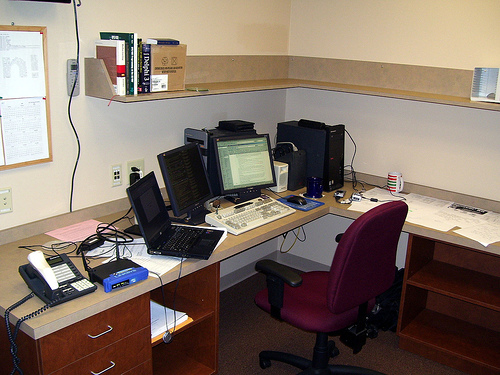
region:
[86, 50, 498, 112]
corner shelf above the desk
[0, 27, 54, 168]
bulletin board with papers on it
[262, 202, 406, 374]
maroon desk chair.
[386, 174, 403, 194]
red and green striped mug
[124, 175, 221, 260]
laptop on the desk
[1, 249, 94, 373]
black and white telephone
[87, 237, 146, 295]
black and blue computer router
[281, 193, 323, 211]
mouse on a blue mousepad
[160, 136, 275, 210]
two desktop computer monitors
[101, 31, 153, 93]
books on the left end of the shelf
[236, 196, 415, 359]
the chair is maroon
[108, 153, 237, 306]
the laptop on the table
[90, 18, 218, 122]
a book on the shelf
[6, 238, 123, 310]
a telephone on the desk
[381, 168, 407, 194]
green and red coffee cup on desk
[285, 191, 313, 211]
black computer mouse on a pad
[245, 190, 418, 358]
red office chair at a desk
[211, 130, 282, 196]
computer monitor on a desk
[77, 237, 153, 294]
black and blue computer router on desk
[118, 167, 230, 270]
laptop computer on a desk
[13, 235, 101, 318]
office telephone on a desk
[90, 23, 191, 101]
books on a shelf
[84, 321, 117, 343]
metal handle on a drawer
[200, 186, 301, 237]
computer keyboard on a desk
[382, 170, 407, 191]
A colorful coffee mug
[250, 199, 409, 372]
A purple office chair with black arms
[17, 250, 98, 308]
A black telephone on the desk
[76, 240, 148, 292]
A black and blue wifi router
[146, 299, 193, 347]
Papers sitting on a shelf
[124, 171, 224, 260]
A black laptop computer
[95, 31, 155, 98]
Books sitting on a shelf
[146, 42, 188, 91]
A cardboard box on the shelf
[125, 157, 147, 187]
A white power outlet on the wall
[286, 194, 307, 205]
A black computer mouse